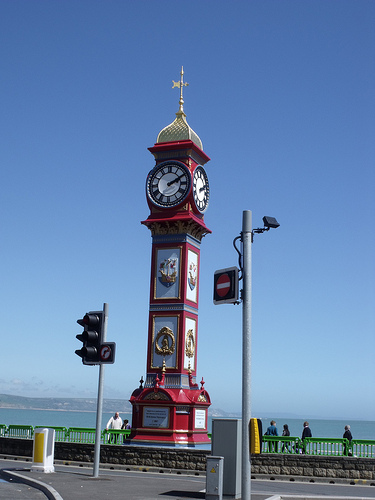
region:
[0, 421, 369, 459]
green metal railing on bridge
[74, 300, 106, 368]
black metal street light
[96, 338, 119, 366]
street sign with symbol meaning no right turn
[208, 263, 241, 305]
street sign of red circle with white line through it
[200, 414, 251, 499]
two gray electrical boxes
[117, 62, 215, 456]
red and white decorative tower with gold steeple top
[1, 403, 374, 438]
view of large body of water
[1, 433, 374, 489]
gray concrete brick bridge barrier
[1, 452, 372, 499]
road curb with rounded edges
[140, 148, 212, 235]
clocks in two sides of tower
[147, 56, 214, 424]
tower near the water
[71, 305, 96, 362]
traffic lights on the sidewalk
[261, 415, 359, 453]
people walking near the water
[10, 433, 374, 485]
wall near the water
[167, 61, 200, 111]
direction tool on top the tower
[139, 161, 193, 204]
clock on one side of tower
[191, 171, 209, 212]
clock on another side of tower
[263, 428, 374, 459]
green fence near water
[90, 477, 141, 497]
sidewalk near the water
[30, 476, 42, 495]
curb on the sidewalk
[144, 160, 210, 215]
Two clock faces on two ten.pm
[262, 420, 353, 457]
Four people by a green fence.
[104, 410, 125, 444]
A man is touching a green fence.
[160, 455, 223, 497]
The gray box is casting a shadow.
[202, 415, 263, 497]
Two gray boxes are by a pole with a yellow/black box.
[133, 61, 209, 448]
The red and white clock tower has royal markings.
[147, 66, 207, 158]
The roof has a spire that is gold.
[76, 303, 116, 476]
The post has a traffic signal on it.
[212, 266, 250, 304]
A red circle with a slash is on a sign.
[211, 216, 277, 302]
A rectangular box is attached to a sign by a wire.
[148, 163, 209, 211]
two clocks on the tower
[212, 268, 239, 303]
electronic street sign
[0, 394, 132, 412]
mountains on the horizon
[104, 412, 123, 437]
man in a white sweater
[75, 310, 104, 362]
three lights on the street signal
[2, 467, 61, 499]
the curb is made of concrete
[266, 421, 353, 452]
people walking on the boardwalk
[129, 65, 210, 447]
a decorative clock tower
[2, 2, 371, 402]
clear blue skies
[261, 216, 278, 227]
solar panel for the street sign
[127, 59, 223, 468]
red, white, and gold clock tower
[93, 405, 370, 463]
people walking along the water front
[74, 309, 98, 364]
three lights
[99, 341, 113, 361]
no turn sign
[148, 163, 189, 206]
black and white clock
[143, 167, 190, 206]
roman numerals around the clock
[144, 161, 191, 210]
clock indicating it's about 2:10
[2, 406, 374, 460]
large body of water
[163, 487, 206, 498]
shadow on the ground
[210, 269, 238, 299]
red, white, and black sign